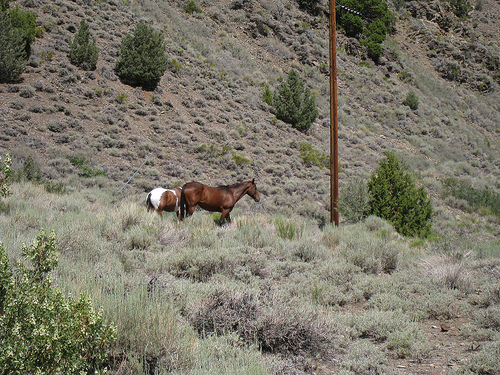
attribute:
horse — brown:
[180, 178, 262, 224]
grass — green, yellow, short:
[1, 179, 499, 373]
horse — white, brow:
[143, 186, 183, 221]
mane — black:
[213, 181, 246, 189]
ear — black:
[249, 178, 257, 185]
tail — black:
[179, 183, 188, 221]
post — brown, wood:
[326, 0, 345, 228]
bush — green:
[113, 19, 170, 92]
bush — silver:
[186, 287, 346, 365]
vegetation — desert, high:
[0, 1, 499, 374]